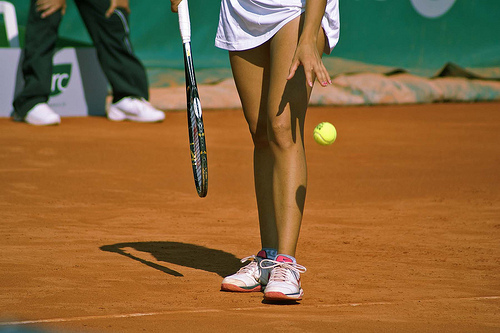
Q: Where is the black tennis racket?
A: In the player's hand.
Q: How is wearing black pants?
A: The person in the background.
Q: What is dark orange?
A: The tennis court.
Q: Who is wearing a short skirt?
A: The tennis player.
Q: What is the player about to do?
A: Serve the ball.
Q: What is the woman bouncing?
A: A tennis ball.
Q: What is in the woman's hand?
A: Tennis racket.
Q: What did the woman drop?
A: Tennis ball.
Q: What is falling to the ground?
A: Tennis ball.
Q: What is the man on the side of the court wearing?
A: Pants and shoes.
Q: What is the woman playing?
A: Tennis.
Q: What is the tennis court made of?
A: Red dirt.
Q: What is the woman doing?
A: Preparing to serve.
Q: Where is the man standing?
A: On the side of the tennis court.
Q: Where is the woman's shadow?
A: On the tennis court.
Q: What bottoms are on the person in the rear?
A: Pants.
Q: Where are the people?
A: On a tennis court.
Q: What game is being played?
A: Tennis.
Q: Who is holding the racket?
A: A woman.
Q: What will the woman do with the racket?
A: Hit the ball.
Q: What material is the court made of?
A: Clay.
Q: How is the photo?
A: Clear.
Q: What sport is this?
A: Tennis.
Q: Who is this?
A: Player.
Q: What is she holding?
A: Racket.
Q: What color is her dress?
A: White.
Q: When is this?
A: Daytime.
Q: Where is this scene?
A: Clay tennis court.